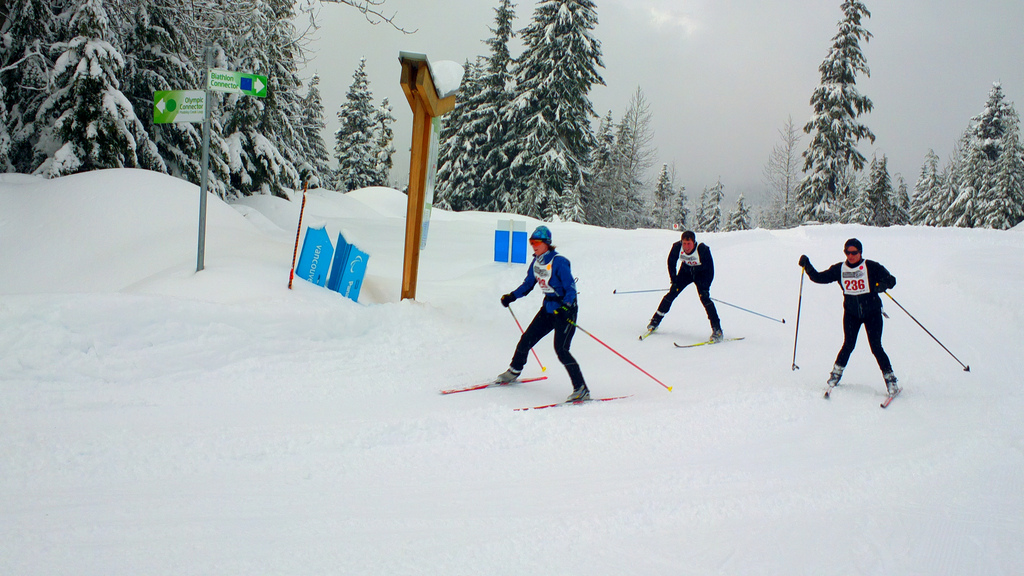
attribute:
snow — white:
[42, 192, 135, 276]